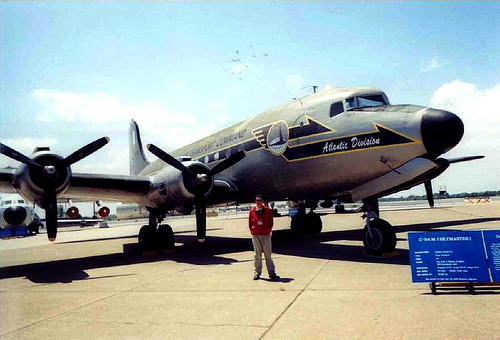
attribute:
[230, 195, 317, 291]
person — standing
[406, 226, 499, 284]
sign — blue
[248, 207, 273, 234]
jacket — red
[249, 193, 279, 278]
man — standing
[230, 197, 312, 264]
coat — red